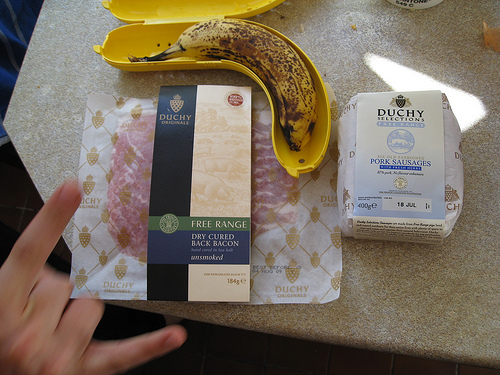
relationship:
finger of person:
[21, 196, 93, 252] [20, 225, 92, 374]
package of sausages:
[332, 87, 470, 243] [356, 83, 491, 273]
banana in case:
[191, 31, 351, 118] [150, 14, 225, 79]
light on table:
[377, 54, 458, 99] [47, 82, 77, 127]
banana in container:
[191, 31, 351, 118] [131, 10, 279, 127]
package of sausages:
[362, 98, 470, 232] [356, 83, 491, 273]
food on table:
[134, 21, 311, 115] [47, 82, 77, 127]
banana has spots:
[191, 31, 351, 118] [245, 48, 314, 96]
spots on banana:
[245, 48, 314, 96] [191, 31, 351, 118]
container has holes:
[131, 10, 279, 127] [149, 32, 186, 51]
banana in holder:
[191, 31, 351, 118] [108, 15, 203, 72]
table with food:
[47, 82, 77, 127] [134, 21, 311, 115]